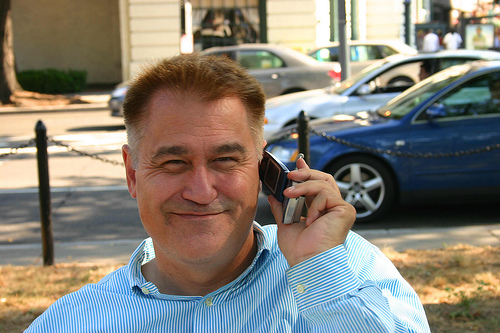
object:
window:
[194, 0, 280, 49]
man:
[22, 50, 434, 333]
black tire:
[321, 151, 397, 224]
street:
[0, 68, 497, 264]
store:
[181, 0, 264, 54]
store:
[404, 0, 463, 51]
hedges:
[13, 66, 89, 96]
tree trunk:
[0, 1, 22, 91]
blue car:
[264, 59, 500, 225]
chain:
[47, 137, 126, 168]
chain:
[266, 124, 300, 148]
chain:
[307, 125, 499, 160]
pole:
[338, 0, 350, 80]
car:
[260, 49, 498, 145]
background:
[0, 0, 499, 332]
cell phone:
[257, 149, 305, 226]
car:
[105, 43, 341, 119]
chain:
[0, 139, 35, 161]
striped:
[233, 297, 305, 332]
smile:
[163, 206, 235, 223]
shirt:
[20, 218, 432, 332]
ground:
[0, 107, 499, 332]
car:
[306, 39, 421, 91]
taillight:
[326, 68, 342, 84]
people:
[419, 23, 441, 54]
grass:
[0, 243, 499, 332]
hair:
[121, 49, 268, 171]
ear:
[121, 143, 135, 202]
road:
[0, 104, 498, 267]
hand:
[265, 156, 358, 262]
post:
[32, 118, 55, 265]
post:
[295, 109, 308, 168]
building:
[0, 0, 417, 91]